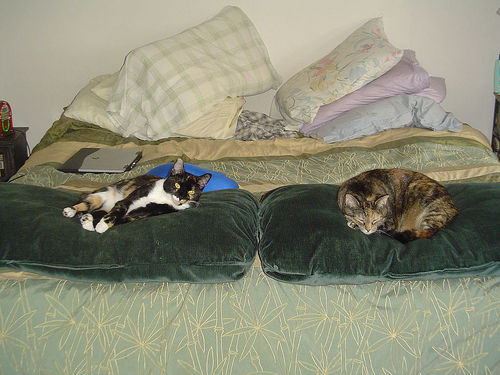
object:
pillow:
[3, 179, 261, 283]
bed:
[0, 106, 499, 369]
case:
[273, 16, 402, 131]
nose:
[365, 227, 371, 233]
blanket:
[8, 117, 490, 371]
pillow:
[125, 4, 281, 123]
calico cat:
[64, 158, 212, 234]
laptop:
[57, 147, 141, 172]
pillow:
[259, 174, 497, 283]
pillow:
[142, 164, 238, 192]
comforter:
[258, 182, 499, 286]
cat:
[335, 167, 457, 243]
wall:
[1, 3, 499, 146]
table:
[0, 124, 28, 181]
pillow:
[274, 18, 404, 131]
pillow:
[298, 48, 430, 134]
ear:
[341, 192, 360, 212]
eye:
[174, 181, 181, 189]